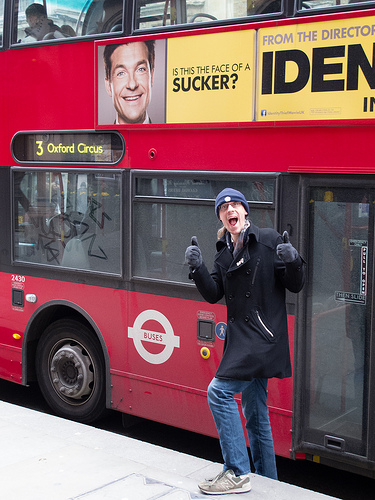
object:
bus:
[2, 2, 373, 488]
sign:
[14, 132, 123, 166]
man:
[185, 188, 304, 495]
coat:
[184, 220, 307, 380]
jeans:
[205, 375, 279, 479]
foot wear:
[196, 461, 249, 497]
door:
[296, 179, 368, 458]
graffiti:
[16, 196, 112, 266]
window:
[13, 167, 122, 278]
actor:
[103, 39, 155, 124]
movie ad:
[99, 22, 374, 121]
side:
[2, 40, 373, 177]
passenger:
[24, 3, 60, 40]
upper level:
[1, 3, 373, 50]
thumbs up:
[185, 230, 295, 268]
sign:
[128, 309, 181, 365]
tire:
[35, 318, 106, 424]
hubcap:
[50, 342, 93, 401]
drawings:
[28, 199, 118, 267]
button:
[198, 344, 210, 357]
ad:
[170, 27, 372, 106]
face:
[220, 201, 245, 231]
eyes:
[213, 201, 242, 213]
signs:
[331, 235, 370, 324]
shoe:
[198, 456, 252, 495]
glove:
[185, 236, 205, 268]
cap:
[214, 188, 249, 223]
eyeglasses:
[215, 199, 251, 214]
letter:
[274, 48, 310, 95]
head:
[215, 186, 250, 234]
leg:
[206, 374, 249, 468]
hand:
[185, 234, 203, 272]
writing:
[18, 174, 112, 270]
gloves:
[276, 230, 298, 263]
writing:
[260, 30, 375, 98]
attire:
[191, 231, 298, 481]